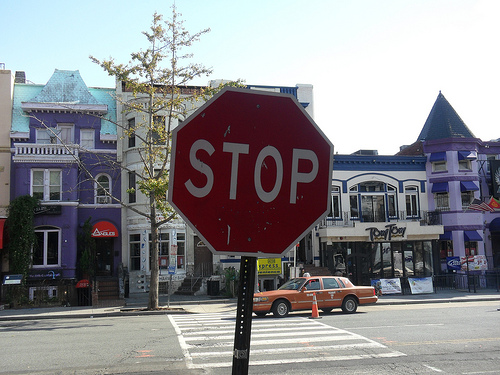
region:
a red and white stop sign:
[162, 80, 332, 372]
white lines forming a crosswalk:
[172, 297, 445, 372]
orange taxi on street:
[245, 265, 410, 321]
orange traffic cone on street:
[300, 281, 341, 346]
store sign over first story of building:
[320, 220, 412, 305]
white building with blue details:
[308, 150, 433, 263]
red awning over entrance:
[85, 215, 120, 285]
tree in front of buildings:
[41, 15, 246, 310]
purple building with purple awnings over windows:
[415, 77, 495, 287]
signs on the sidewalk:
[371, 266, 441, 301]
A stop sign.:
[170, 81, 335, 266]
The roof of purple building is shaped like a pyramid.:
[406, 80, 496, 295]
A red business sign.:
[85, 217, 117, 238]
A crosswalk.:
[165, 310, 435, 370]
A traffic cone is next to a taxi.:
[240, 265, 390, 325]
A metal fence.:
[2, 276, 92, 306]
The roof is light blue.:
[10, 72, 120, 143]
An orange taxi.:
[250, 270, 376, 316]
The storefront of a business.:
[322, 221, 437, 292]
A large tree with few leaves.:
[46, 20, 252, 311]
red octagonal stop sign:
[164, 85, 334, 260]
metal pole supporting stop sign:
[228, 256, 259, 373]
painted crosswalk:
[165, 312, 442, 372]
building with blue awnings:
[415, 92, 498, 291]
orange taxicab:
[254, 272, 379, 314]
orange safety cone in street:
[308, 292, 320, 320]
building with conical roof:
[416, 89, 493, 289]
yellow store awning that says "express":
[257, 257, 284, 274]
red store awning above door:
[90, 220, 120, 238]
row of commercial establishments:
[1, 65, 497, 302]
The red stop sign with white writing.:
[165, 85, 333, 371]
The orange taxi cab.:
[253, 268, 378, 316]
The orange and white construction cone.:
[308, 292, 323, 319]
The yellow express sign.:
[257, 254, 284, 276]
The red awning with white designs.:
[90, 220, 122, 238]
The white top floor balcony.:
[13, 139, 80, 164]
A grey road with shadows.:
[0, 318, 175, 373]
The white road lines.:
[177, 313, 444, 372]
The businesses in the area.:
[313, 88, 496, 302]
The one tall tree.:
[21, 3, 246, 313]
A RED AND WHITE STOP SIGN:
[162, 78, 339, 367]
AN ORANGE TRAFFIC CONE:
[302, 283, 329, 323]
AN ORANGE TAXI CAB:
[241, 267, 386, 321]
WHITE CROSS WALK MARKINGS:
[163, 299, 453, 374]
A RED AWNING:
[82, 216, 131, 242]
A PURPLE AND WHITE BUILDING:
[12, 101, 122, 309]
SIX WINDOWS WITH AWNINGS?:
[416, 146, 497, 266]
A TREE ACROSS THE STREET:
[78, 30, 253, 317]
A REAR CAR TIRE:
[338, 290, 363, 316]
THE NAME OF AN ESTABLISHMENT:
[361, 220, 425, 249]